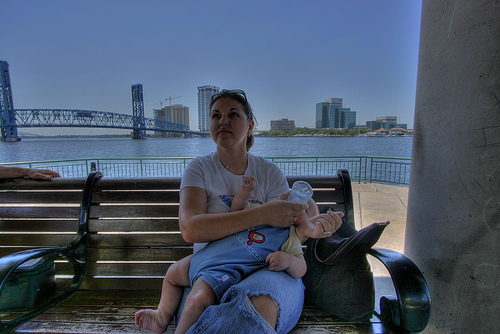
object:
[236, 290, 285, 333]
hole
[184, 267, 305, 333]
blue color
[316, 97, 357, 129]
building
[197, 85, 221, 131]
building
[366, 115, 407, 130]
building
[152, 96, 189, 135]
building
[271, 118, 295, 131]
building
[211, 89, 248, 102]
glasses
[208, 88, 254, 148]
head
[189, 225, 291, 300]
dress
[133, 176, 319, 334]
baby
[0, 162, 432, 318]
bench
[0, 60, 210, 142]
bridge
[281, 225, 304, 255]
shirt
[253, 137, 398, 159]
water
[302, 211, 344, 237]
fingers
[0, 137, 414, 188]
water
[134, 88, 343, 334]
lady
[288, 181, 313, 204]
baby bottle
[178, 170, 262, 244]
arms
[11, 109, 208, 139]
background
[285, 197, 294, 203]
mouth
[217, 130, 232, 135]
mouth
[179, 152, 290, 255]
shirt